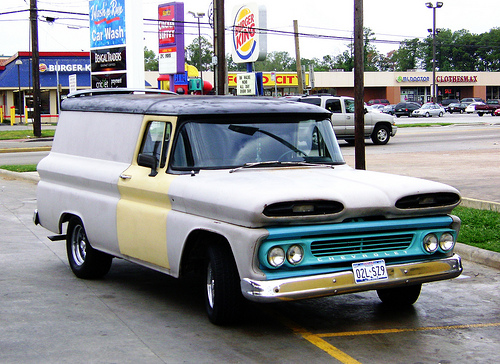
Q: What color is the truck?
A: Gray, black, yellow, and blue.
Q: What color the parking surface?
A: Gray.